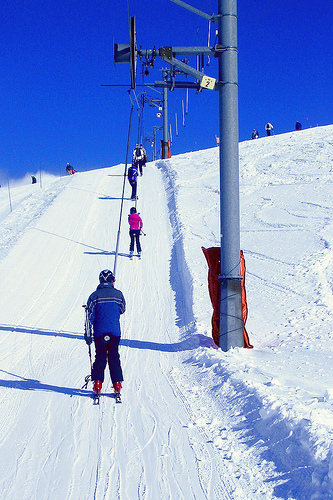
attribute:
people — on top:
[238, 118, 324, 141]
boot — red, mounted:
[91, 380, 101, 394]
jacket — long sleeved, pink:
[127, 212, 142, 230]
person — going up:
[125, 162, 143, 200]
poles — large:
[172, 47, 290, 401]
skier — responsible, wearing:
[82, 267, 126, 403]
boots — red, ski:
[85, 366, 135, 398]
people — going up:
[82, 146, 160, 404]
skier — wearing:
[72, 298, 143, 400]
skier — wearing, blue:
[106, 199, 159, 265]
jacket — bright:
[120, 214, 144, 228]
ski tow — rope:
[104, 69, 172, 133]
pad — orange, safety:
[195, 243, 254, 351]